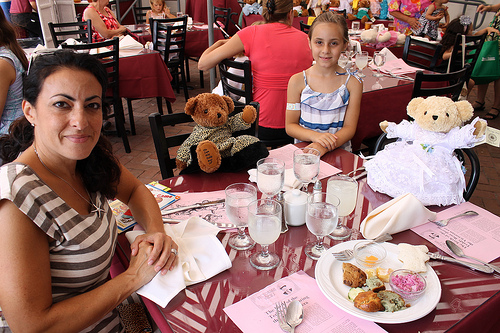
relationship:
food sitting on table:
[332, 241, 460, 319] [94, 151, 399, 275]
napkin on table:
[358, 190, 441, 241] [106, 137, 498, 329]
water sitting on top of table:
[249, 220, 276, 242] [23, 29, 170, 115]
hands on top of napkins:
[121, 225, 181, 284] [118, 209, 233, 305]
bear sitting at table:
[173, 90, 270, 180] [106, 137, 498, 329]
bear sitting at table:
[363, 92, 488, 203] [106, 137, 498, 329]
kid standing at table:
[284, 13, 367, 161] [162, 173, 402, 305]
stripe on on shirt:
[48, 227, 116, 284] [0, 162, 126, 333]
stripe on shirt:
[48, 227, 116, 284] [5, 156, 162, 323]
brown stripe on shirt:
[6, 162, 17, 184] [3, 160, 118, 330]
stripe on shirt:
[48, 227, 116, 284] [3, 160, 118, 330]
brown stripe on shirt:
[27, 185, 61, 222] [0, 153, 128, 327]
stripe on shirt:
[48, 227, 116, 284] [0, 153, 128, 327]